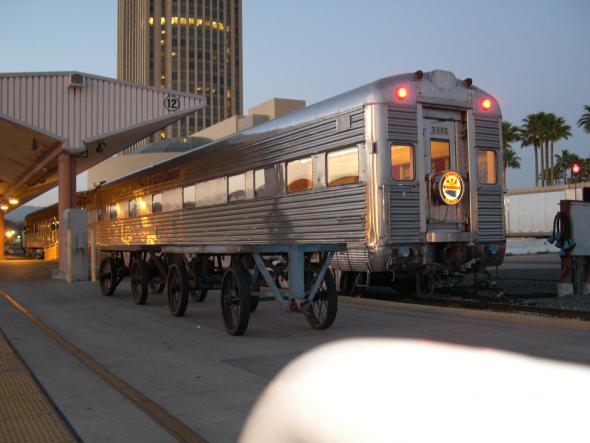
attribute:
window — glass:
[220, 165, 252, 203]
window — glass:
[123, 191, 140, 223]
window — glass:
[93, 144, 359, 216]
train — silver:
[21, 67, 511, 293]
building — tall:
[117, 3, 241, 146]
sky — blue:
[3, 1, 588, 189]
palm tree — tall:
[519, 110, 571, 185]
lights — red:
[396, 82, 494, 110]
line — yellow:
[2, 284, 202, 440]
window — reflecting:
[326, 145, 361, 182]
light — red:
[564, 157, 580, 177]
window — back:
[470, 141, 505, 186]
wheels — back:
[213, 242, 354, 335]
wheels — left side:
[88, 247, 285, 346]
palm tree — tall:
[519, 109, 572, 199]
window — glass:
[467, 139, 504, 192]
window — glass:
[322, 132, 372, 189]